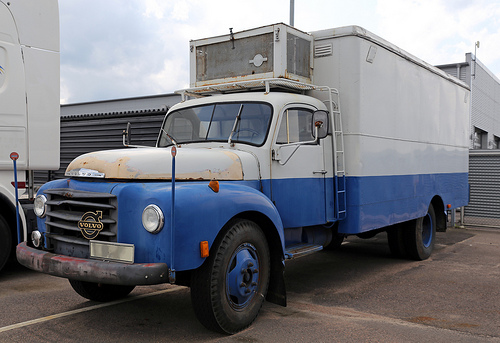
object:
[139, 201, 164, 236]
light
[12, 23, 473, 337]
truck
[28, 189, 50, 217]
light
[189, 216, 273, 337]
tire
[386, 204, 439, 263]
tire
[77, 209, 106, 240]
emblem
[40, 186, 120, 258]
grid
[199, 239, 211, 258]
reflector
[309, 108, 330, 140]
mirror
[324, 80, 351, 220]
ladder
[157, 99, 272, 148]
windows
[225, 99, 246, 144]
wipers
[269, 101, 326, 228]
door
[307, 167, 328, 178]
handle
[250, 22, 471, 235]
side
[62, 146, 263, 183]
hood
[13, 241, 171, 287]
bumper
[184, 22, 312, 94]
unit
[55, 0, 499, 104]
clouds